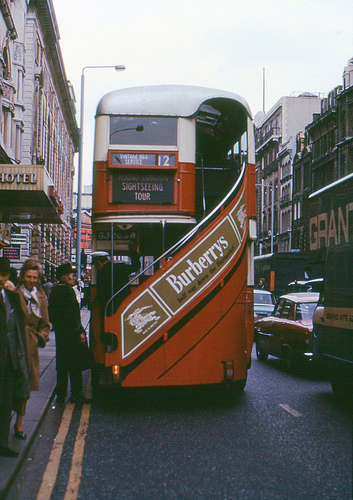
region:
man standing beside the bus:
[46, 257, 122, 397]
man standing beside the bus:
[46, 238, 130, 394]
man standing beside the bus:
[46, 236, 106, 393]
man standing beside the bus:
[49, 248, 97, 407]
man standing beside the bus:
[46, 250, 106, 412]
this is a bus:
[86, 98, 273, 407]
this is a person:
[44, 254, 104, 417]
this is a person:
[17, 258, 62, 389]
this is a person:
[1, 258, 38, 459]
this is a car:
[257, 274, 326, 381]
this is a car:
[255, 287, 273, 328]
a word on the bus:
[152, 231, 234, 294]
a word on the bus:
[128, 187, 157, 207]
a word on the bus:
[116, 179, 176, 201]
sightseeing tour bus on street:
[91, 88, 250, 389]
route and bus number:
[110, 152, 176, 166]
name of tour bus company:
[171, 231, 234, 295]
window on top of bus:
[110, 114, 178, 146]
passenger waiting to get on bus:
[51, 262, 94, 402]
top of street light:
[81, 58, 128, 84]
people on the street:
[3, 254, 41, 454]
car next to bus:
[256, 292, 319, 360]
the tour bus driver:
[91, 252, 128, 305]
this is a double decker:
[35, 38, 334, 413]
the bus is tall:
[64, 70, 265, 447]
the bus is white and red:
[83, 81, 220, 388]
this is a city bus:
[77, 133, 221, 354]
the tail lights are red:
[102, 349, 266, 395]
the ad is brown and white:
[141, 225, 254, 308]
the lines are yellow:
[54, 406, 116, 492]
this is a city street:
[27, 235, 299, 400]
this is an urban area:
[18, 93, 279, 424]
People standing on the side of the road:
[0, 257, 95, 455]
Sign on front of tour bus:
[107, 148, 177, 203]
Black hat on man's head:
[53, 262, 75, 277]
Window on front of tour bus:
[109, 114, 178, 146]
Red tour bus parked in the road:
[89, 84, 258, 397]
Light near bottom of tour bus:
[112, 364, 118, 374]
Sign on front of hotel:
[1, 164, 66, 223]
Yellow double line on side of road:
[35, 368, 90, 498]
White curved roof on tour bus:
[97, 84, 250, 115]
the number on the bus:
[156, 154, 171, 165]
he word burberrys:
[165, 235, 226, 296]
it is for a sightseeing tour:
[119, 179, 166, 200]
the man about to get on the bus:
[53, 267, 89, 402]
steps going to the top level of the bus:
[97, 158, 248, 385]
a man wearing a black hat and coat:
[45, 255, 95, 406]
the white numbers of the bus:
[151, 149, 173, 170]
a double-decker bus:
[81, 79, 261, 401]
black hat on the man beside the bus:
[51, 260, 76, 281]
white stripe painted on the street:
[272, 397, 302, 425]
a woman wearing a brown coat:
[9, 256, 45, 440]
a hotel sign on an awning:
[0, 168, 34, 183]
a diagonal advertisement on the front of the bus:
[110, 189, 251, 362]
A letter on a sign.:
[163, 272, 184, 293]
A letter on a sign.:
[177, 272, 192, 291]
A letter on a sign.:
[187, 259, 203, 275]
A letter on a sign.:
[194, 257, 206, 268]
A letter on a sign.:
[201, 252, 215, 265]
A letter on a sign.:
[205, 246, 217, 264]